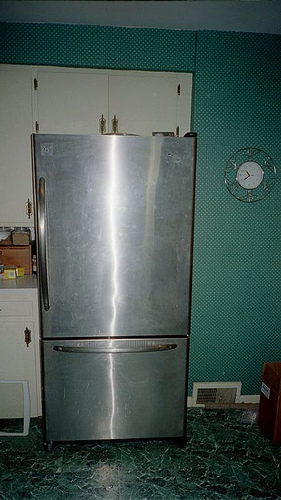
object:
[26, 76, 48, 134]
hinges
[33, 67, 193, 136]
cabinet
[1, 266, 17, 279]
box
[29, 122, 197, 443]
freezer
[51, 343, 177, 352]
handle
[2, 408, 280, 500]
floor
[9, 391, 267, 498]
tile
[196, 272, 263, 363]
paper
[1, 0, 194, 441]
wall paper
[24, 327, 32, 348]
door handle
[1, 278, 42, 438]
cabinet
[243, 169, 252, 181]
handles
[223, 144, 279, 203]
clock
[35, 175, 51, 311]
handle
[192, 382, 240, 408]
vents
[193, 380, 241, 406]
air vent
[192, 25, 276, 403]
wall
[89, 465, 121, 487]
spot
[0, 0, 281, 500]
area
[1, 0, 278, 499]
house